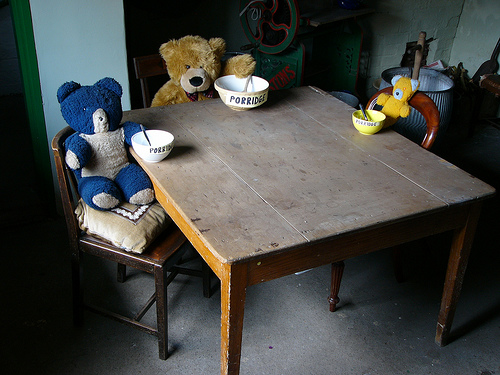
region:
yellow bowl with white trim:
[351, 107, 386, 137]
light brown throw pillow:
[75, 194, 166, 255]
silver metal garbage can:
[376, 64, 453, 135]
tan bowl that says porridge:
[213, 71, 270, 111]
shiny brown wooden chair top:
[366, 85, 436, 146]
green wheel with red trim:
[238, 3, 301, 58]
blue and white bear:
[55, 72, 156, 212]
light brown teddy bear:
[150, 33, 255, 105]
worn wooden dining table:
[112, 82, 494, 372]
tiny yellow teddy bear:
[375, 71, 419, 128]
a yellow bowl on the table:
[344, 103, 387, 138]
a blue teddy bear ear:
[56, 76, 82, 104]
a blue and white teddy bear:
[52, 78, 157, 217]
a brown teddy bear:
[148, 34, 255, 110]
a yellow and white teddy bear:
[374, 69, 424, 128]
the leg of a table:
[211, 283, 252, 374]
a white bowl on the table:
[124, 123, 186, 165]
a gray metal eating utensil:
[135, 120, 155, 147]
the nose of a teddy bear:
[186, 71, 208, 89]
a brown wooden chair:
[49, 124, 216, 364]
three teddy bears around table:
[61, 22, 428, 229]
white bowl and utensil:
[124, 115, 177, 166]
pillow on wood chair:
[68, 183, 170, 265]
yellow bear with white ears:
[374, 70, 422, 120]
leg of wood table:
[204, 290, 260, 360]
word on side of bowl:
[219, 83, 270, 113]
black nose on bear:
[183, 74, 212, 91]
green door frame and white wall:
[11, 14, 71, 91]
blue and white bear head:
[54, 75, 126, 137]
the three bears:
[64, 34, 495, 123]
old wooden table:
[165, 104, 437, 299]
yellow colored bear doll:
[383, 74, 448, 158]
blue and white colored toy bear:
[41, 76, 175, 230]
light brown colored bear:
[180, 26, 324, 124]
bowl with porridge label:
[223, 70, 292, 119]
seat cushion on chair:
[76, 193, 201, 315]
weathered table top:
[236, 160, 398, 221]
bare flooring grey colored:
[282, 317, 447, 372]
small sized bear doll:
[380, 64, 423, 143]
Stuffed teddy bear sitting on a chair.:
[55, 80, 151, 211]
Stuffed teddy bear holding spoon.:
[145, 25, 267, 112]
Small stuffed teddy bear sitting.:
[348, 70, 418, 137]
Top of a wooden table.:
[122, 78, 494, 265]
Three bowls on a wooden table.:
[127, 72, 420, 164]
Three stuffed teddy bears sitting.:
[43, 27, 456, 215]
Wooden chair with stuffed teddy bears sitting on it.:
[44, 128, 179, 363]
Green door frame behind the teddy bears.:
[11, 0, 51, 200]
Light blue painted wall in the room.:
[28, 3, 138, 130]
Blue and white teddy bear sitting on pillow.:
[59, 78, 166, 256]